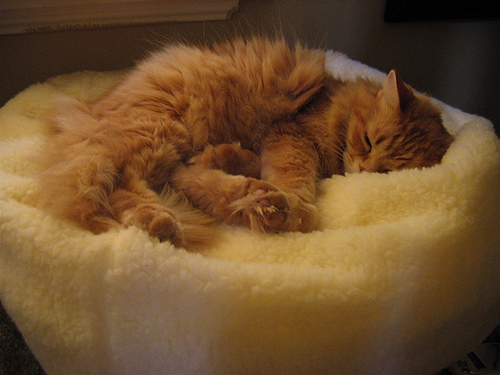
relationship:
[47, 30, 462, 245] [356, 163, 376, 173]
cat has nose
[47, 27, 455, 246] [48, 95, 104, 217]
cat has tail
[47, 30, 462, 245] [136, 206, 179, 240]
cat has paw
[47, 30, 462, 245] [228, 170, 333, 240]
cat has paw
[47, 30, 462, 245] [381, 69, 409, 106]
cat has ear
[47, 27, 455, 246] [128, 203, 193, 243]
cat has paws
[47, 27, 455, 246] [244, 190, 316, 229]
cat has paw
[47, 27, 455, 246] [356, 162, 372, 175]
cat has nose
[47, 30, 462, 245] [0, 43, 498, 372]
cat sleeping on bed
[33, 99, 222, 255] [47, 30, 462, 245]
tail of a cat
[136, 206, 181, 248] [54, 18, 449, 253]
paw of cat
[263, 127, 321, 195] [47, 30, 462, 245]
leg of cat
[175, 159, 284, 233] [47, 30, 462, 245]
leg of cat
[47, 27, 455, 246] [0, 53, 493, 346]
cat sleeping on bed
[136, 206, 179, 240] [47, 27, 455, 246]
paw of cat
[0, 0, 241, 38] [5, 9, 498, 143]
white trim with wall